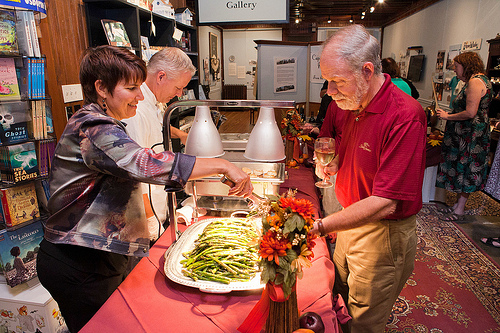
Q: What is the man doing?
A: Getting food.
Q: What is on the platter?
A: Asparagus.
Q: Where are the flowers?
A: Near the food.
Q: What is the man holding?
A: A drink.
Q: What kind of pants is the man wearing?
A: Khaki.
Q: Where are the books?
A: On the shelf.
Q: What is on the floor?
A: A rug.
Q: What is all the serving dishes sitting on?
A: A table.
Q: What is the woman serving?
A: Asparagus.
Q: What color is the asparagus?
A: Green.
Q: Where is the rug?
A: The floor.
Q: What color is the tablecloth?
A: Red.